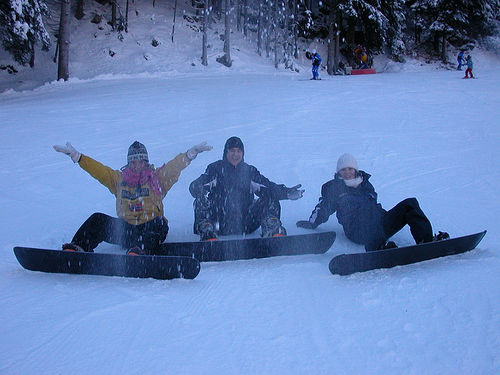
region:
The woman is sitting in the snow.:
[8, 126, 215, 284]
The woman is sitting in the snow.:
[292, 140, 494, 287]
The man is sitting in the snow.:
[145, 122, 340, 270]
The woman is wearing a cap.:
[9, 123, 211, 289]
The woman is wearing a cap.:
[289, 144, 494, 285]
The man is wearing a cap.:
[156, 118, 340, 278]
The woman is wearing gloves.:
[11, 130, 214, 289]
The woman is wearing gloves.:
[283, 151, 496, 279]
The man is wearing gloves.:
[151, 125, 341, 267]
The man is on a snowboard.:
[143, 126, 338, 270]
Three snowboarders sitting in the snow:
[4, 110, 496, 313]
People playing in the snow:
[294, 26, 499, 121]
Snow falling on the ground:
[51, 0, 291, 90]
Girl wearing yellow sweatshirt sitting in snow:
[6, 130, 213, 285]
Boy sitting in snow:
[200, 132, 303, 271]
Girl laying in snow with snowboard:
[300, 146, 499, 291]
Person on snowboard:
[293, 35, 333, 92]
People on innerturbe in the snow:
[341, 33, 386, 85]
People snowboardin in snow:
[441, 38, 487, 93]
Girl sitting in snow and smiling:
[111, 136, 169, 248]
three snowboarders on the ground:
[51, 131, 447, 264]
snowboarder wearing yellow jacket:
[58, 133, 212, 260]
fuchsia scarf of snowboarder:
[119, 160, 159, 196]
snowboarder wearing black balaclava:
[193, 137, 304, 239]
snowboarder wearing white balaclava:
[296, 150, 445, 256]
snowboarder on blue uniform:
[306, 48, 325, 79]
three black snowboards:
[14, 230, 492, 278]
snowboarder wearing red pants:
[461, 55, 477, 76]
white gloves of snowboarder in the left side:
[53, 141, 212, 175]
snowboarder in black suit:
[190, 138, 301, 238]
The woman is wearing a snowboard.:
[10, 117, 214, 292]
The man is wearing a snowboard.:
[154, 123, 339, 267]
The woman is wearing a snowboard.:
[296, 137, 494, 283]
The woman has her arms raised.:
[8, 117, 213, 289]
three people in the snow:
[1, 79, 480, 316]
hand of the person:
[279, 178, 313, 208]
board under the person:
[328, 220, 493, 295]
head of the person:
[313, 135, 383, 195]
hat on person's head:
[332, 143, 364, 168]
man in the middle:
[186, 112, 306, 244]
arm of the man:
[42, 132, 118, 187]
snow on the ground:
[185, 286, 301, 359]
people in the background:
[236, 22, 488, 123]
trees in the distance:
[166, 6, 315, 73]